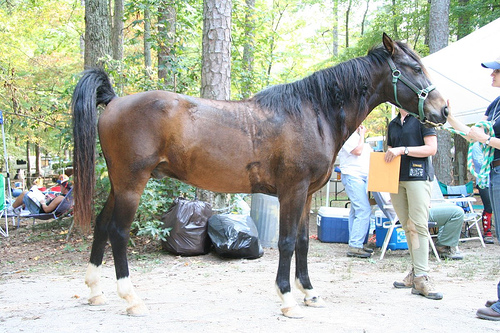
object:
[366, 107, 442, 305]
man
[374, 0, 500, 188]
tree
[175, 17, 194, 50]
leaves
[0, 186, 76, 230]
chair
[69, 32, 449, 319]
brown horse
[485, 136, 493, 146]
watch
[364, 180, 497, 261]
chair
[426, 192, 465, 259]
person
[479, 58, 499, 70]
cap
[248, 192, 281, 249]
can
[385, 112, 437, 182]
shirt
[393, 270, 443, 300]
shoes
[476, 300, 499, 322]
shoes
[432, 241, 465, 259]
shoes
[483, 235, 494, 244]
shoes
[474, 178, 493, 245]
person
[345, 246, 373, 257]
shoes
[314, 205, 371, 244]
trunk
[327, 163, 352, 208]
table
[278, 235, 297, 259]
knee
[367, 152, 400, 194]
envelope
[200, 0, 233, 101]
tree trunk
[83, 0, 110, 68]
tree trunk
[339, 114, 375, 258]
people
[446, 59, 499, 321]
people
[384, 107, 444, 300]
person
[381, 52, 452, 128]
bridle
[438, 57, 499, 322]
girl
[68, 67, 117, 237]
tail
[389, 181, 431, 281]
pants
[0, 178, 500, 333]
ground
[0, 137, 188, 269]
park area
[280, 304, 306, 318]
part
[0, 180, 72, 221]
person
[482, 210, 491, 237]
sock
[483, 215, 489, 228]
dots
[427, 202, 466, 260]
man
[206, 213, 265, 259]
trash bag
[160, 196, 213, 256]
trash bag